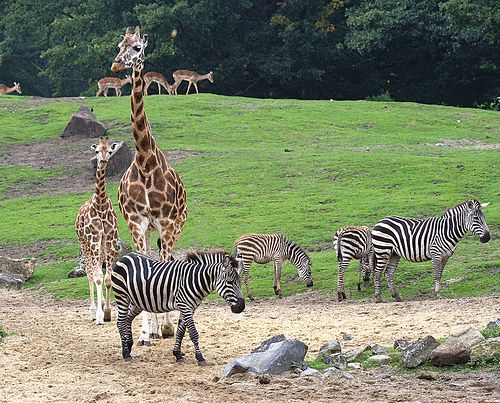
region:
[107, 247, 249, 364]
Zebra standing in dirt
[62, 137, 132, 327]
Giraffe standing in dirt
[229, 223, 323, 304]
Zebra grazing on grass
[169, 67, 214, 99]
Deer standing on hill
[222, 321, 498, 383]
Pile of rocks in dirt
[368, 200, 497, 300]
Zebra standing in grass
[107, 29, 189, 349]
Giraffe standing in dirt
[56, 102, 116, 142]
Large rock on hill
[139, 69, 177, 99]
Deer grazing on grass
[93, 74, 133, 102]
Deer standing on grass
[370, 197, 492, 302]
a zebra standing on field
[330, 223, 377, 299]
a zebra standing on field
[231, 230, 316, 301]
a zebra grazing grass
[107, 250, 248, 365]
a zebra walking in dirt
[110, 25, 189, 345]
a giraffe walking in dirt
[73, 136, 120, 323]
a giraffe walking in dirt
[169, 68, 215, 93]
a deer walking on hill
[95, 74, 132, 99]
a deer walking on hill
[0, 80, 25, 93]
a deer walking on hill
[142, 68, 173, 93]
a deer grazing on hill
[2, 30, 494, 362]
animals walking outside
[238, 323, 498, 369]
rocks in the ground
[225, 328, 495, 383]
the rocks are gray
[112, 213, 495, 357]
zebras are outside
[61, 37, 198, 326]
giraffes are near the zebras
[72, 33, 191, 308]
the giraffes are brown and tan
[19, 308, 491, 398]
the dirt is a tan color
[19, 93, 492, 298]
pretty green grass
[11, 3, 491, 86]
trees near the animals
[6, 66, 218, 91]
deer are near the trees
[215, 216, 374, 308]
two zebra grazing together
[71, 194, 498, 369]
four zebra together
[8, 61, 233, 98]
deer grazing on a hill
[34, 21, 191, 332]
two giraffe walking together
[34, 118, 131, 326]
baby giraffe walking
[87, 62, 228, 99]
three deer walking together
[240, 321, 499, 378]
rocks with grass growing around them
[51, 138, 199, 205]
rock in bald spot of the grass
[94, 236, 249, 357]
zebra walking infront of giraffe's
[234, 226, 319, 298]
smallest zebra grazing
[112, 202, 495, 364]
A group of zebras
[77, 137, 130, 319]
A small young giraffe looking at the camera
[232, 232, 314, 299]
A zebra bending over to graze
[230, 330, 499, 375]
Small rocks among the grass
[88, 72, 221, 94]
Small deer behind the giraffes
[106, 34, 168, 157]
The long neck of a giraffe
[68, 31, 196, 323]
An adult giraffe and a baby giraffe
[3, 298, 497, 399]
An area of tan dirt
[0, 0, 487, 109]
A line of trees around the clearing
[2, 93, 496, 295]
Patchy grass on the ground